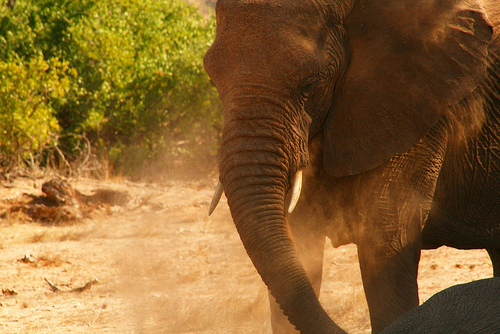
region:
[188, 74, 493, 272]
the elephant is brown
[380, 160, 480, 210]
the skin is wrinkled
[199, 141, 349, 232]
the tusk are white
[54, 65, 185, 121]
the bush is green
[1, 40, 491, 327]
photo was taken in africa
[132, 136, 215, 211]
there is sand in air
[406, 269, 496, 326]
the elephant is the smallest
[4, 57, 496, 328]
the scene is outdoors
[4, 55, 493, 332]
the photo was taken during daytime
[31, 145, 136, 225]
tree branches are on the ground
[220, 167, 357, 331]
The elephant has a long trunk.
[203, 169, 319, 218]
The tusks are white.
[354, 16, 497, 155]
The elephant has a big ear.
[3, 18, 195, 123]
The tree is green.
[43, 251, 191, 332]
There is dirt on the ground.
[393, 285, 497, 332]
Another elephant next to the big one.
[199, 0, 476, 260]
The elephant is brown.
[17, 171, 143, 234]
A large clump of dirt.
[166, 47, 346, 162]
The elephant is looking down.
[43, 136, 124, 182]
The twigs are brown.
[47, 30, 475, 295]
dust blowing around elephant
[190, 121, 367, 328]
trunk curled to one side of head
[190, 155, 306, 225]
small and curved white tusks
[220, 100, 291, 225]
rings of wrinkles along trunk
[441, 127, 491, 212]
curved and short lines across body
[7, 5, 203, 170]
yellowish green leaves on full bush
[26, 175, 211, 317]
dry and flat brown ground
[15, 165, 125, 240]
brown object on ground in two pieces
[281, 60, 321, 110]
small eye inside circle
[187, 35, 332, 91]
bumps above the eye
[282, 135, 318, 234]
elephant tusk is white and yellow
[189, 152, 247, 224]
elephant tusk is white and yellow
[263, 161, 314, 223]
elephant tusk is white and yellow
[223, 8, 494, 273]
this is an elephant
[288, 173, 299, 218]
this is a tusk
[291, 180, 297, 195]
the tusk is white in color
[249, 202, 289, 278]
this is a trunk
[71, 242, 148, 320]
this is a ground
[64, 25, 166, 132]
this is a tree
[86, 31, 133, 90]
the tree has green leaves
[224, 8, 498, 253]
the elephant is huge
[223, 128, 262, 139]
this is a line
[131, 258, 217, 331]
these are dry grass